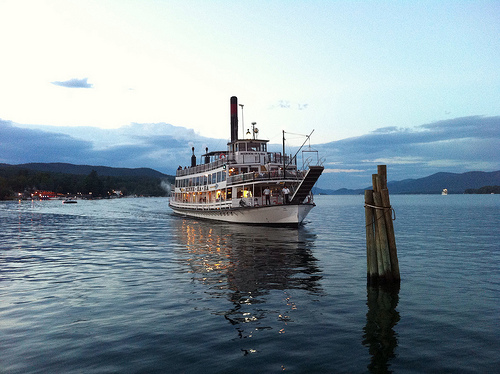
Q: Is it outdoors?
A: Yes, it is outdoors.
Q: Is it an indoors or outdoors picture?
A: It is outdoors.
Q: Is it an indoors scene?
A: No, it is outdoors.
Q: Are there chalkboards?
A: No, there are no chalkboards.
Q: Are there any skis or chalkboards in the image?
A: No, there are no chalkboards or skis.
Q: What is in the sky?
A: The clouds are in the sky.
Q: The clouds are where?
A: The clouds are in the sky.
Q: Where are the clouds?
A: The clouds are in the sky.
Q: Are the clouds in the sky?
A: Yes, the clouds are in the sky.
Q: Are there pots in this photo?
A: No, there are no pots.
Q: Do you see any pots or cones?
A: No, there are no pots or cones.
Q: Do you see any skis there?
A: No, there are no skis.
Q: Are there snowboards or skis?
A: No, there are no skis or snowboards.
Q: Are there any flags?
A: No, there are no flags.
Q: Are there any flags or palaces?
A: No, there are no flags or palaces.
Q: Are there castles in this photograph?
A: No, there are no castles.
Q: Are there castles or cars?
A: No, there are no castles or cars.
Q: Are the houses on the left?
A: Yes, the houses are on the left of the image.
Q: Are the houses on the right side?
A: No, the houses are on the left of the image.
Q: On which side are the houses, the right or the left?
A: The houses are on the left of the image.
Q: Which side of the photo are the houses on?
A: The houses are on the left of the image.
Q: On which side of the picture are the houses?
A: The houses are on the left of the image.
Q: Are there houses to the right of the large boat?
A: No, the houses are to the left of the boat.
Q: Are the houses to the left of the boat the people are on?
A: Yes, the houses are to the left of the boat.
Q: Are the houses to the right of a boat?
A: No, the houses are to the left of a boat.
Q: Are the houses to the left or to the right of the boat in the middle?
A: The houses are to the left of the boat.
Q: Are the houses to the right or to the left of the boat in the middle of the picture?
A: The houses are to the left of the boat.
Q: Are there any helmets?
A: No, there are no helmets.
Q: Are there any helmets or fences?
A: No, there are no helmets or fences.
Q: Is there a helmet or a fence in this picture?
A: No, there are no helmets or fences.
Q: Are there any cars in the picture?
A: No, there are no cars.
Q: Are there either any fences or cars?
A: No, there are no cars or fences.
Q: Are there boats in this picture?
A: Yes, there is a boat.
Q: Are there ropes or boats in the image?
A: Yes, there is a boat.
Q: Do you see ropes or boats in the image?
A: Yes, there is a boat.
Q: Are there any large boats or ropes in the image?
A: Yes, there is a large boat.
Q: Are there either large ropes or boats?
A: Yes, there is a large boat.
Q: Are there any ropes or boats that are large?
A: Yes, the boat is large.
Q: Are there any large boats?
A: Yes, there is a large boat.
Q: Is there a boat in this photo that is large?
A: Yes, there is a boat that is large.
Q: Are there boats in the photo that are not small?
A: Yes, there is a large boat.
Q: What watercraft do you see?
A: The watercraft is a boat.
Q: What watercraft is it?
A: The watercraft is a boat.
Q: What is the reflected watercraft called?
A: The watercraft is a boat.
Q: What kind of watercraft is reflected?
A: The watercraft is a boat.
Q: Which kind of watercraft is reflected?
A: The watercraft is a boat.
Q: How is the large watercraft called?
A: The watercraft is a boat.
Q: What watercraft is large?
A: The watercraft is a boat.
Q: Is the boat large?
A: Yes, the boat is large.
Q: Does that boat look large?
A: Yes, the boat is large.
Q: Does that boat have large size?
A: Yes, the boat is large.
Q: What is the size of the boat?
A: The boat is large.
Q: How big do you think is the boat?
A: The boat is large.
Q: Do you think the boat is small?
A: No, the boat is large.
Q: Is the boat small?
A: No, the boat is large.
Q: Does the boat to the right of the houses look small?
A: No, the boat is large.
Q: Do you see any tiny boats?
A: No, there is a boat but it is large.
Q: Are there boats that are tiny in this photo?
A: No, there is a boat but it is large.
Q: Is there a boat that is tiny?
A: No, there is a boat but it is large.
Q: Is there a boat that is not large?
A: No, there is a boat but it is large.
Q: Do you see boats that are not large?
A: No, there is a boat but it is large.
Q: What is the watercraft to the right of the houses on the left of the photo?
A: The watercraft is a boat.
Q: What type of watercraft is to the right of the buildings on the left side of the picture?
A: The watercraft is a boat.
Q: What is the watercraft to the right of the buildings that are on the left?
A: The watercraft is a boat.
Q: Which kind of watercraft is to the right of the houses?
A: The watercraft is a boat.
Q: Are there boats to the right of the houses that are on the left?
A: Yes, there is a boat to the right of the houses.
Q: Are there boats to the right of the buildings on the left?
A: Yes, there is a boat to the right of the houses.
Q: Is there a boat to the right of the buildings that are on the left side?
A: Yes, there is a boat to the right of the houses.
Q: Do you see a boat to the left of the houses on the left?
A: No, the boat is to the right of the houses.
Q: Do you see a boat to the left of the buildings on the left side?
A: No, the boat is to the right of the houses.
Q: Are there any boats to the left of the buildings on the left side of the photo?
A: No, the boat is to the right of the houses.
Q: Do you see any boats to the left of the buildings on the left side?
A: No, the boat is to the right of the houses.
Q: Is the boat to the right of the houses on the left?
A: Yes, the boat is to the right of the houses.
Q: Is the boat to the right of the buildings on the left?
A: Yes, the boat is to the right of the houses.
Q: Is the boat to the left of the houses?
A: No, the boat is to the right of the houses.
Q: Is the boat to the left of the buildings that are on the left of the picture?
A: No, the boat is to the right of the houses.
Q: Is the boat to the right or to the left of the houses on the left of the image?
A: The boat is to the right of the houses.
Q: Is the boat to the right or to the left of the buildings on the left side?
A: The boat is to the right of the houses.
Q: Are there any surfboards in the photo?
A: No, there are no surfboards.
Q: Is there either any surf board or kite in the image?
A: No, there are no surfboards or kites.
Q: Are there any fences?
A: No, there are no fences.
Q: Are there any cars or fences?
A: No, there are no fences or cars.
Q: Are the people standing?
A: Yes, the people are standing.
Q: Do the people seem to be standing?
A: Yes, the people are standing.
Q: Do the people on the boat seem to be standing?
A: Yes, the people are standing.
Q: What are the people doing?
A: The people are standing.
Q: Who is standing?
A: The people are standing.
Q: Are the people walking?
A: No, the people are standing.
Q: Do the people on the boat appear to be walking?
A: No, the people are standing.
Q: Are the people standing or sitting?
A: The people are standing.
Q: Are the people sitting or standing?
A: The people are standing.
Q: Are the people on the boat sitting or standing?
A: The people are standing.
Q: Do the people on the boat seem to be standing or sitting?
A: The people are standing.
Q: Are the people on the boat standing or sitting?
A: The people are standing.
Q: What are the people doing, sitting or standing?
A: The people are standing.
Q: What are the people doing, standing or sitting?
A: The people are standing.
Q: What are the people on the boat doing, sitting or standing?
A: The people are standing.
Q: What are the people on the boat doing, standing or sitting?
A: The people are standing.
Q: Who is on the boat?
A: The people are on the boat.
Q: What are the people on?
A: The people are on the boat.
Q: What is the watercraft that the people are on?
A: The watercraft is a boat.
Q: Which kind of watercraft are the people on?
A: The people are on the boat.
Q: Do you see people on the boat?
A: Yes, there are people on the boat.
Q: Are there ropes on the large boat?
A: No, there are people on the boat.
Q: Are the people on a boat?
A: Yes, the people are on a boat.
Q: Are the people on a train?
A: No, the people are on a boat.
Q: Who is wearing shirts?
A: The people are wearing shirts.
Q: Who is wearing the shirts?
A: The people are wearing shirts.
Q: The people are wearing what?
A: The people are wearing shirts.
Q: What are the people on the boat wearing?
A: The people are wearing shirts.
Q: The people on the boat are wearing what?
A: The people are wearing shirts.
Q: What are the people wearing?
A: The people are wearing shirts.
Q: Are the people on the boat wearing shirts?
A: Yes, the people are wearing shirts.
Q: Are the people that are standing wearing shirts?
A: Yes, the people are wearing shirts.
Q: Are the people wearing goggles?
A: No, the people are wearing shirts.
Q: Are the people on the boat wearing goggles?
A: No, the people are wearing shirts.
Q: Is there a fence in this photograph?
A: No, there are no fences.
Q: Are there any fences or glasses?
A: No, there are no fences or glasses.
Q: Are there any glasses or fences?
A: No, there are no fences or glasses.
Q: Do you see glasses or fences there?
A: No, there are no fences or glasses.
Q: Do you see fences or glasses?
A: No, there are no fences or glasses.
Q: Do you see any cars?
A: No, there are no cars.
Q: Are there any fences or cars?
A: No, there are no cars or fences.